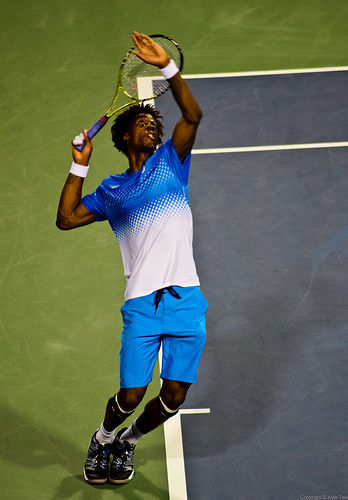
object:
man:
[55, 29, 210, 486]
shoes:
[84, 424, 136, 485]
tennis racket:
[73, 34, 183, 151]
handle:
[71, 128, 94, 166]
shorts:
[119, 285, 210, 388]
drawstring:
[152, 286, 182, 315]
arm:
[159, 54, 203, 164]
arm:
[55, 171, 103, 231]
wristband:
[157, 58, 179, 80]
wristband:
[69, 160, 89, 178]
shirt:
[81, 138, 200, 301]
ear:
[122, 129, 129, 143]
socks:
[96, 417, 146, 447]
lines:
[134, 66, 347, 499]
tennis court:
[1, 1, 346, 499]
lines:
[135, 66, 346, 155]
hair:
[110, 102, 165, 157]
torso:
[99, 146, 201, 293]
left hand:
[132, 30, 168, 67]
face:
[129, 113, 158, 153]